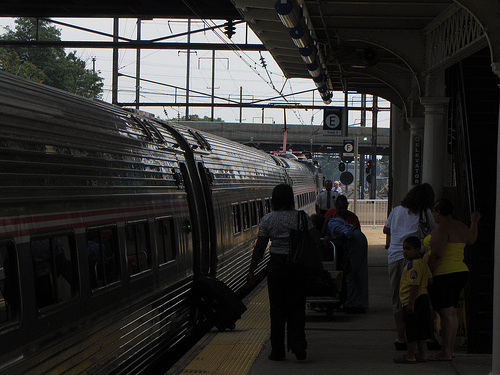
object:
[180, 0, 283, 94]
lines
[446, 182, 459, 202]
ground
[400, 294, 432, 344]
shorts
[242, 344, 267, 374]
line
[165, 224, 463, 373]
pavement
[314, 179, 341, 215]
man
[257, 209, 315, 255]
shirt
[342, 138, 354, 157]
sign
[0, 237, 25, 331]
windows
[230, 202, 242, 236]
windows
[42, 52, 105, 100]
trees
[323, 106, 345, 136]
sign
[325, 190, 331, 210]
tie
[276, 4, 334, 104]
pole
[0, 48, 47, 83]
tree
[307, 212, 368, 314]
people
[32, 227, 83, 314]
window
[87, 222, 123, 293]
window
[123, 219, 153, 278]
window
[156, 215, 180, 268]
window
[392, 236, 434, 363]
boy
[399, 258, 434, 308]
yellow shirt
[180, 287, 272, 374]
yellow line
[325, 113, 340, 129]
circle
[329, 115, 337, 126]
e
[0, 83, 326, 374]
train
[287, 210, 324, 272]
purse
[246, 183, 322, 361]
lady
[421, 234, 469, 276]
shirt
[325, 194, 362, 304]
people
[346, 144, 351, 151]
letter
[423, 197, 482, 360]
lady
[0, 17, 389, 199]
scaffolding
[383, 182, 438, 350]
people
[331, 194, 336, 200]
badge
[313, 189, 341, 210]
shirt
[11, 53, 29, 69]
leaves